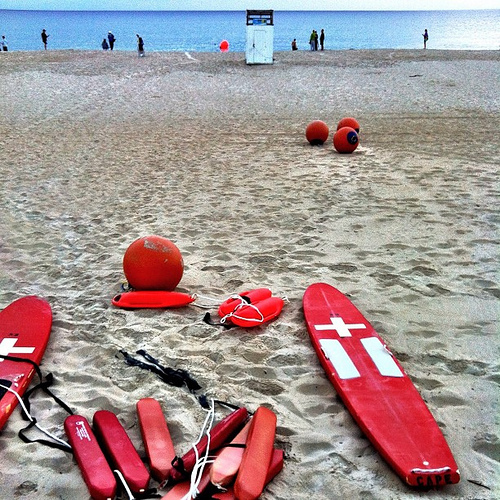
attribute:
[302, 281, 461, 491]
rescue board — red, a red surfboard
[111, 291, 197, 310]
life jacket floaty — red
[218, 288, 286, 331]
floating buoy's — red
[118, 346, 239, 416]
straps — black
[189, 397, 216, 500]
straps — white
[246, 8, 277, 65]
lifeguard tower — black, for lifeguard,  white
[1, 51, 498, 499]
sand — brown, tan, foot prints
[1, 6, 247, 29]
ocean — blue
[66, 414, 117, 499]
floaty — red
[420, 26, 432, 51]
peson — fishing, standing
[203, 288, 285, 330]
strap —  Black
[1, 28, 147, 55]
people — standing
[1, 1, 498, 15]
sky — clear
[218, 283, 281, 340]
pad —  for saving